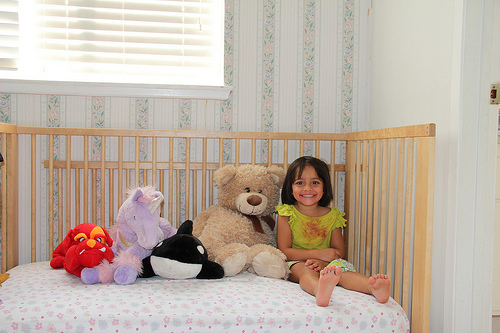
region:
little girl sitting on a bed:
[275, 156, 391, 305]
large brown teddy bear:
[191, 165, 284, 277]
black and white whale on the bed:
[138, 220, 224, 280]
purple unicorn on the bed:
[82, 188, 177, 288]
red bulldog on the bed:
[49, 222, 114, 275]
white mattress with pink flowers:
[1, 261, 411, 331]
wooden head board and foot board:
[0, 120, 437, 330]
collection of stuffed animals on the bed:
[48, 164, 283, 284]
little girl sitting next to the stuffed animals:
[275, 156, 395, 308]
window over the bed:
[0, 0, 230, 91]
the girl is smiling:
[228, 129, 383, 329]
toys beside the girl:
[11, 140, 434, 330]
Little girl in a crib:
[8, 115, 460, 321]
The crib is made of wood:
[2, 106, 469, 330]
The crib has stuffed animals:
[23, 118, 286, 308]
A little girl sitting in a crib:
[263, 148, 404, 321]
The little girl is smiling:
[288, 188, 333, 201]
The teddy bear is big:
[187, 155, 297, 290]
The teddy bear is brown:
[194, 155, 286, 295]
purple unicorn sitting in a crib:
[97, 183, 190, 293]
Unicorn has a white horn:
[143, 186, 173, 223]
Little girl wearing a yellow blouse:
[259, 190, 365, 274]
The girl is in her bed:
[217, 140, 493, 326]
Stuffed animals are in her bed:
[77, 164, 357, 271]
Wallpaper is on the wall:
[27, 95, 448, 252]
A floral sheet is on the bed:
[55, 278, 379, 325]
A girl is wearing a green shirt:
[265, 193, 350, 258]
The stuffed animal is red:
[28, 219, 135, 266]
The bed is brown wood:
[72, 111, 334, 271]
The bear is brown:
[172, 142, 338, 324]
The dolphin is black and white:
[145, 205, 239, 304]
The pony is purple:
[102, 188, 184, 328]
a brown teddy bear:
[192, 150, 289, 266]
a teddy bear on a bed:
[162, 150, 274, 270]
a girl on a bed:
[272, 146, 379, 266]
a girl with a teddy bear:
[190, 145, 371, 277]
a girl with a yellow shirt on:
[251, 178, 372, 273]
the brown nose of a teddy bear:
[243, 187, 268, 212]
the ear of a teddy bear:
[213, 150, 243, 192]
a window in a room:
[14, 4, 238, 139]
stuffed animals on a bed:
[54, 165, 316, 267]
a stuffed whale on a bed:
[134, 208, 244, 280]